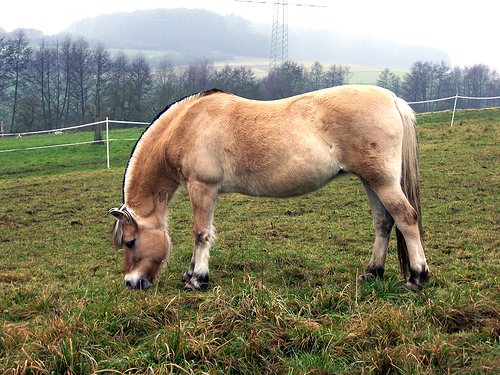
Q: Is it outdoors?
A: Yes, it is outdoors.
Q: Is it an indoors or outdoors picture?
A: It is outdoors.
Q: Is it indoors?
A: No, it is outdoors.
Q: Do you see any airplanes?
A: No, there are no airplanes.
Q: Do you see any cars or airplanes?
A: No, there are no airplanes or cars.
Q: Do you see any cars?
A: No, there are no cars.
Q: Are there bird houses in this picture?
A: No, there are no bird houses.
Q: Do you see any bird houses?
A: No, there are no bird houses.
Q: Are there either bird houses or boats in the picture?
A: No, there are no bird houses or boats.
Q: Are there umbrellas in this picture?
A: No, there are no umbrellas.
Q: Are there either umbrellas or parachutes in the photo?
A: No, there are no umbrellas or parachutes.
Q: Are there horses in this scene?
A: Yes, there is a horse.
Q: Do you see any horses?
A: Yes, there is a horse.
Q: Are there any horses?
A: Yes, there is a horse.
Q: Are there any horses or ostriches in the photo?
A: Yes, there is a horse.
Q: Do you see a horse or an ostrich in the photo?
A: Yes, there is a horse.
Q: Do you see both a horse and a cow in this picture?
A: No, there is a horse but no cows.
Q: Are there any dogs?
A: No, there are no dogs.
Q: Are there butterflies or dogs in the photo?
A: No, there are no dogs or butterflies.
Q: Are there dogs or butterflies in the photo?
A: No, there are no dogs or butterflies.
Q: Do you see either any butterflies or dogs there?
A: No, there are no dogs or butterflies.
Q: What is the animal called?
A: The animal is a horse.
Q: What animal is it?
A: The animal is a horse.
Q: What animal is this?
A: This is a horse.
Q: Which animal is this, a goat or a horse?
A: This is a horse.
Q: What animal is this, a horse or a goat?
A: This is a horse.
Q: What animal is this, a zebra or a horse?
A: This is a horse.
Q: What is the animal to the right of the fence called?
A: The animal is a horse.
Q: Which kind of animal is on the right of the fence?
A: The animal is a horse.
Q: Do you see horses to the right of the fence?
A: Yes, there is a horse to the right of the fence.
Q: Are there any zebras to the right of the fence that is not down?
A: No, there is a horse to the right of the fence.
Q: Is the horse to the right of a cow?
A: No, the horse is to the right of the fence.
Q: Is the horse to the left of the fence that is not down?
A: No, the horse is to the right of the fence.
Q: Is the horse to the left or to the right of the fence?
A: The horse is to the right of the fence.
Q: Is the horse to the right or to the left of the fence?
A: The horse is to the right of the fence.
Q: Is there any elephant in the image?
A: No, there are no elephants.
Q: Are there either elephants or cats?
A: No, there are no elephants or cats.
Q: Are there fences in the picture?
A: Yes, there is a fence.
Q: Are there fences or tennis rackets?
A: Yes, there is a fence.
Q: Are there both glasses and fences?
A: No, there is a fence but no glasses.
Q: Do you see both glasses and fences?
A: No, there is a fence but no glasses.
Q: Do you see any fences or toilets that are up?
A: Yes, the fence is up.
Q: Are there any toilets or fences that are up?
A: Yes, the fence is up.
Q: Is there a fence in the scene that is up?
A: Yes, there is a fence that is up.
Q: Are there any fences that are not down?
A: Yes, there is a fence that is up.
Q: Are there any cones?
A: No, there are no cones.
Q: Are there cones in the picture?
A: No, there are no cones.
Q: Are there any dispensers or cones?
A: No, there are no cones or dispensers.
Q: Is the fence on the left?
A: Yes, the fence is on the left of the image.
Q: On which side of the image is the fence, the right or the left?
A: The fence is on the left of the image.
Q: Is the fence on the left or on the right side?
A: The fence is on the left of the image.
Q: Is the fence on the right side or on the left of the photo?
A: The fence is on the left of the image.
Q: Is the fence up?
A: Yes, the fence is up.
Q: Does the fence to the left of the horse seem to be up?
A: Yes, the fence is up.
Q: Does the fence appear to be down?
A: No, the fence is up.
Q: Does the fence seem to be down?
A: No, the fence is up.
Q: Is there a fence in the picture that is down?
A: No, there is a fence but it is up.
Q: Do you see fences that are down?
A: No, there is a fence but it is up.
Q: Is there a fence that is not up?
A: No, there is a fence but it is up.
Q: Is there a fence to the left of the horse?
A: Yes, there is a fence to the left of the horse.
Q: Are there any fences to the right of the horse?
A: No, the fence is to the left of the horse.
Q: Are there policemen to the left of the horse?
A: No, there is a fence to the left of the horse.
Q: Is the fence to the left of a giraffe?
A: No, the fence is to the left of the horse.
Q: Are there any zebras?
A: No, there are no zebras.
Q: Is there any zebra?
A: No, there are no zebras.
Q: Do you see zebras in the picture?
A: No, there are no zebras.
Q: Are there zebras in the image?
A: No, there are no zebras.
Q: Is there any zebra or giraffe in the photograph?
A: No, there are no zebras or giraffes.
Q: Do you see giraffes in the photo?
A: No, there are no giraffes.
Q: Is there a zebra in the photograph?
A: No, there are no zebras.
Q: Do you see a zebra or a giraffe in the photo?
A: No, there are no zebras or giraffes.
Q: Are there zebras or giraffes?
A: No, there are no zebras or giraffes.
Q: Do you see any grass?
A: Yes, there is grass.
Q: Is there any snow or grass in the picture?
A: Yes, there is grass.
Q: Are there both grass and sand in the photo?
A: No, there is grass but no sand.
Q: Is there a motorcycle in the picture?
A: No, there are no motorcycles.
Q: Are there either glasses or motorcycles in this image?
A: No, there are no motorcycles or glasses.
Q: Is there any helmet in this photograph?
A: No, there are no helmets.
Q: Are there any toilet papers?
A: No, there are no toilet papers.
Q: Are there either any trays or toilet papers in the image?
A: No, there are no toilet papers or trays.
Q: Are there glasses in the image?
A: No, there are no glasses.